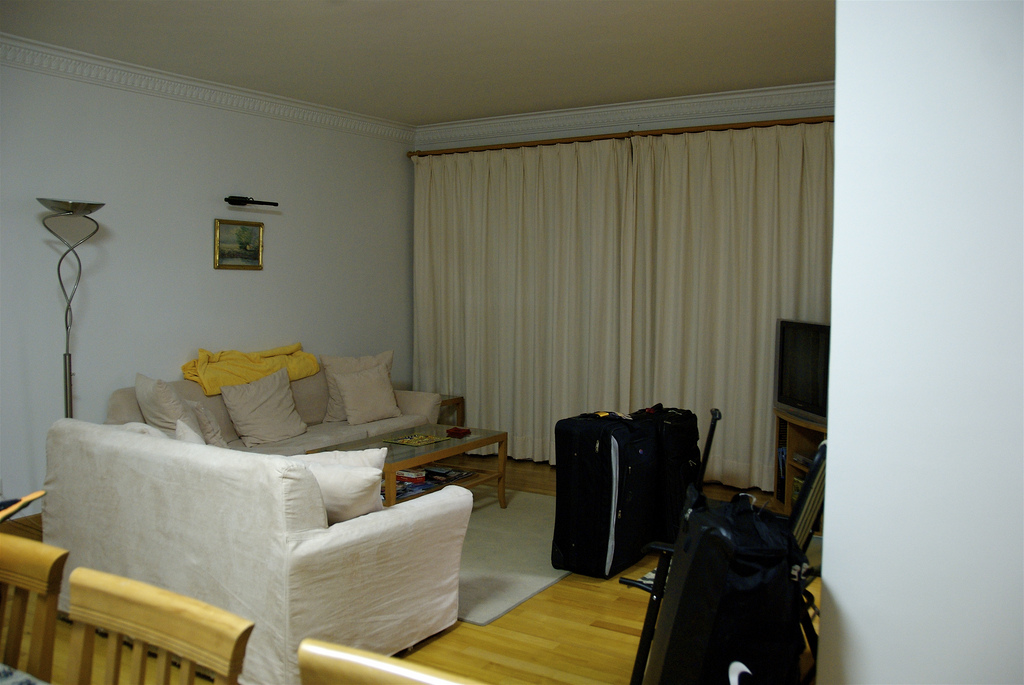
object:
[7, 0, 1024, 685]
building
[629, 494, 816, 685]
suitcases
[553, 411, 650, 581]
suitcase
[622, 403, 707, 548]
suitcase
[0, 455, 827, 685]
ground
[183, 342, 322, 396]
blanket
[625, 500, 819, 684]
luggage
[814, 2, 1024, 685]
wall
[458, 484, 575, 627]
rug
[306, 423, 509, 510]
table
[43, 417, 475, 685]
loveseat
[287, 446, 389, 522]
pillow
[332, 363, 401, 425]
pillow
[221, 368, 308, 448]
pillow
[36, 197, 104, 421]
lamp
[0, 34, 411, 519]
wall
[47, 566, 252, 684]
chair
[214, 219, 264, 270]
picture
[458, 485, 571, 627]
carpet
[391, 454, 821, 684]
floor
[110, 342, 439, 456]
couch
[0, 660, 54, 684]
table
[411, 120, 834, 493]
window